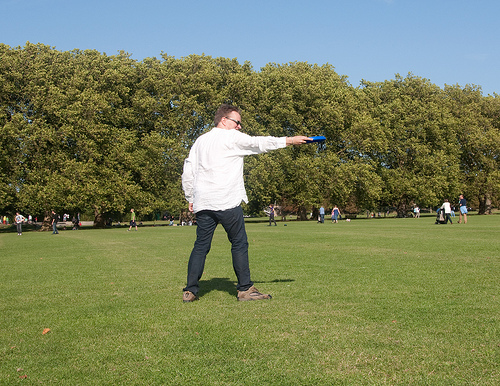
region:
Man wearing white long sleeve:
[162, 91, 314, 319]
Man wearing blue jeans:
[166, 94, 325, 309]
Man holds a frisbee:
[163, 94, 335, 317]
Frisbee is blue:
[301, 124, 334, 151]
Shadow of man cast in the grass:
[202, 268, 293, 308]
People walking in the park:
[265, 181, 497, 236]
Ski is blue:
[5, 1, 497, 76]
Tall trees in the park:
[10, 51, 491, 211]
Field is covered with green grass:
[9, 214, 499, 377]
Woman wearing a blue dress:
[328, 199, 346, 226]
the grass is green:
[128, 316, 295, 381]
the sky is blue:
[318, 10, 440, 60]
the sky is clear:
[322, 0, 458, 62]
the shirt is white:
[177, 125, 288, 216]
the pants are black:
[176, 207, 269, 299]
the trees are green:
[24, 72, 122, 198]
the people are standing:
[433, 192, 475, 229]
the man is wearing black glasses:
[212, 106, 247, 130]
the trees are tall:
[25, 46, 132, 241]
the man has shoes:
[168, 266, 283, 321]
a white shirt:
[177, 120, 273, 210]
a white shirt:
[439, 200, 452, 213]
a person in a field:
[173, 98, 311, 303]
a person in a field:
[456, 191, 471, 223]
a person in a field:
[443, 194, 456, 227]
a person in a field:
[328, 199, 348, 224]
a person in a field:
[316, 200, 328, 225]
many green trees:
[1, 43, 495, 220]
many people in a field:
[9, 95, 479, 300]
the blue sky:
[0, 0, 497, 122]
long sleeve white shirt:
[180, 126, 288, 213]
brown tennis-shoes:
[180, 283, 272, 302]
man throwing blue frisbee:
[181, 108, 327, 302]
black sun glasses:
[223, 115, 240, 124]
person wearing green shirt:
[126, 206, 138, 231]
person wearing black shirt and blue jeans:
[48, 209, 58, 234]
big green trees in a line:
[1, 42, 498, 231]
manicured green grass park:
[0, 208, 499, 382]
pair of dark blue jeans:
[182, 204, 253, 296]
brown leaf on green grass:
[41, 325, 48, 336]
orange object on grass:
[25, 321, 75, 348]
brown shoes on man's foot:
[231, 287, 278, 308]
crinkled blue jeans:
[175, 197, 307, 279]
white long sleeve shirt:
[175, 122, 302, 213]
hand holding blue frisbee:
[300, 128, 352, 165]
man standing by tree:
[43, 201, 73, 240]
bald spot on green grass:
[289, 311, 335, 361]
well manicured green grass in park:
[23, 247, 133, 300]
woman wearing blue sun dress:
[325, 202, 360, 235]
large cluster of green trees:
[89, 13, 495, 176]